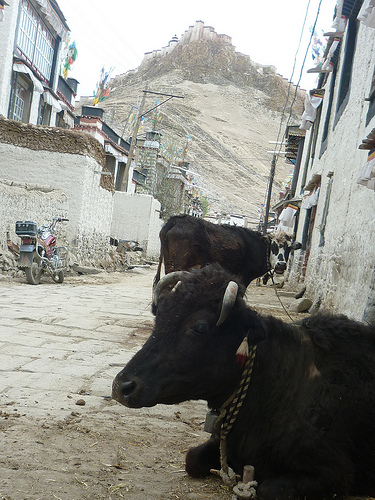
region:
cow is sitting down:
[99, 267, 374, 495]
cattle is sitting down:
[110, 265, 373, 498]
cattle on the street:
[111, 205, 374, 496]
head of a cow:
[104, 269, 260, 410]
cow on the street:
[154, 204, 289, 315]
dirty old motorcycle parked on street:
[15, 211, 73, 287]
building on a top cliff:
[83, 15, 304, 131]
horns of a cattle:
[210, 280, 247, 328]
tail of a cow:
[152, 237, 169, 293]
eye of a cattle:
[189, 317, 213, 338]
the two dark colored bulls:
[110, 213, 373, 499]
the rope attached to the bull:
[207, 344, 255, 498]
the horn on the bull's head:
[216, 280, 236, 325]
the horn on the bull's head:
[152, 271, 195, 306]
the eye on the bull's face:
[190, 321, 211, 333]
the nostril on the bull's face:
[120, 379, 138, 396]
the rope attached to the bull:
[265, 242, 293, 322]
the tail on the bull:
[152, 220, 175, 297]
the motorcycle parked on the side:
[14, 217, 69, 285]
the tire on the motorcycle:
[24, 258, 42, 284]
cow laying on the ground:
[101, 258, 373, 499]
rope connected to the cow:
[216, 381, 256, 496]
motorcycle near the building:
[5, 215, 75, 291]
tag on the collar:
[226, 328, 251, 368]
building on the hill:
[134, 12, 247, 72]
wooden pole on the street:
[134, 86, 184, 131]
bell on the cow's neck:
[198, 410, 224, 436]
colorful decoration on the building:
[88, 64, 114, 106]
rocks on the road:
[60, 392, 100, 419]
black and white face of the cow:
[268, 232, 303, 279]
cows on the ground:
[136, 189, 366, 491]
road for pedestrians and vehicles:
[6, 278, 267, 491]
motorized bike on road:
[9, 204, 71, 281]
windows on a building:
[16, 8, 54, 67]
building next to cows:
[283, 10, 374, 299]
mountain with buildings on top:
[107, 13, 290, 204]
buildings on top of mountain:
[138, 16, 240, 48]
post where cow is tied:
[230, 460, 258, 496]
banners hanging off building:
[277, 198, 300, 224]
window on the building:
[12, 88, 30, 120]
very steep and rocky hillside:
[179, 51, 259, 209]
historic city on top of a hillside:
[96, 9, 308, 120]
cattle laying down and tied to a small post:
[109, 268, 374, 498]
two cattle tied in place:
[109, 208, 373, 497]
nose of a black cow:
[104, 354, 152, 416]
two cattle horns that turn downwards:
[145, 269, 244, 330]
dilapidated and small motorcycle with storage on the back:
[9, 211, 73, 288]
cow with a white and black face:
[261, 226, 303, 277]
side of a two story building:
[269, 0, 374, 315]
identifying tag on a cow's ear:
[230, 308, 269, 369]